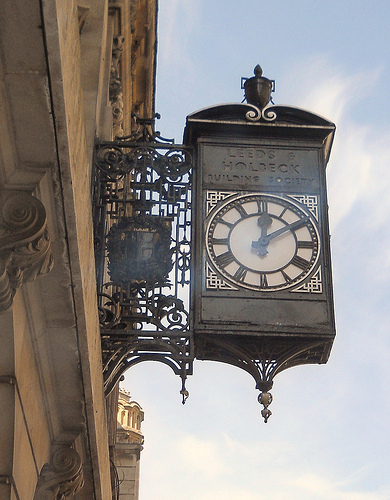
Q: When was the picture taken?
A: Daytime.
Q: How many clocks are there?
A: One.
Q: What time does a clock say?
A: 12:10.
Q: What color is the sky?
A: Blue.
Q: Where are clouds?
A: In the sky.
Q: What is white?
A: Clock's face.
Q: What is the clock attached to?
A: A building.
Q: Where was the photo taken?
A: Side is a building.